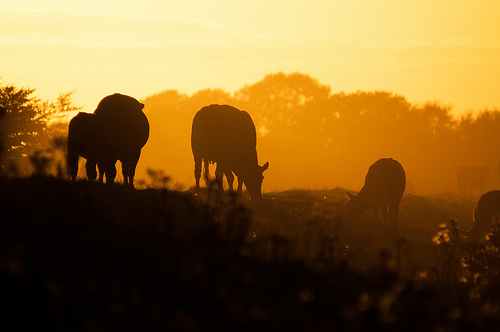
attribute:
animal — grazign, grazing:
[191, 102, 267, 210]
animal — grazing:
[65, 94, 152, 189]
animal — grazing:
[341, 156, 412, 246]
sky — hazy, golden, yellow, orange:
[0, 1, 499, 80]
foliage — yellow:
[238, 66, 498, 143]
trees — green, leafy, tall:
[2, 85, 63, 148]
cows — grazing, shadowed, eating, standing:
[60, 90, 144, 190]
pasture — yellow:
[53, 177, 495, 223]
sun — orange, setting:
[0, 9, 9, 19]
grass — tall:
[165, 186, 279, 303]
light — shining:
[21, 12, 441, 80]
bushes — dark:
[18, 226, 428, 321]